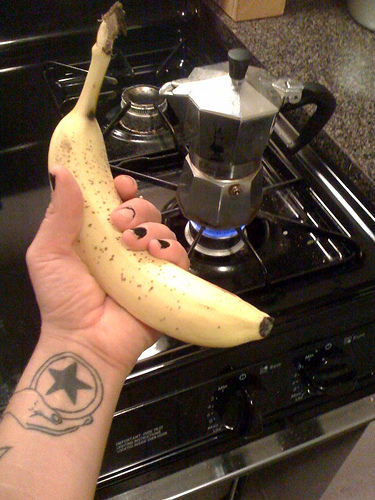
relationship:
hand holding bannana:
[25, 212, 100, 500] [59, 114, 253, 325]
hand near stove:
[25, 212, 100, 500] [208, 212, 370, 430]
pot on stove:
[176, 62, 287, 194] [208, 212, 370, 430]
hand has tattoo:
[25, 212, 100, 500] [6, 349, 103, 454]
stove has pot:
[208, 212, 370, 430] [176, 62, 287, 194]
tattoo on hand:
[6, 349, 103, 454] [25, 212, 100, 500]